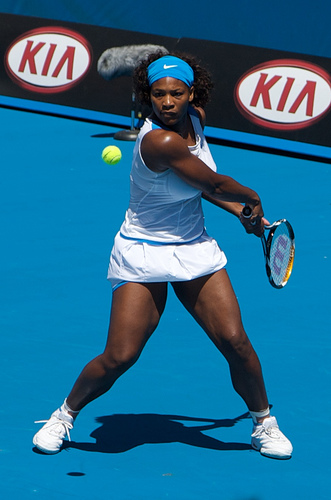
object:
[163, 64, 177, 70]
logo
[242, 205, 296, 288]
racket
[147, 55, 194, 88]
headband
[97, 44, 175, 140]
stand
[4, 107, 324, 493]
floor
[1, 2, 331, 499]
tennis court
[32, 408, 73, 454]
shoe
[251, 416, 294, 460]
shoe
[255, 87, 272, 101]
ground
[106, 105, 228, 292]
dress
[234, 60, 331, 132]
advertisement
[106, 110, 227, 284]
white dress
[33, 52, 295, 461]
lady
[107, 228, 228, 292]
skirt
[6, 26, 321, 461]
court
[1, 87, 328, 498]
ground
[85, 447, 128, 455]
shade edge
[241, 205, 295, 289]
tennis racket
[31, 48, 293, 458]
tennis player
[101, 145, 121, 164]
ball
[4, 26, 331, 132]
sign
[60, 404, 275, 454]
shadow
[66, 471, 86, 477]
shadow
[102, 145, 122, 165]
base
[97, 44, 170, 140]
furry stool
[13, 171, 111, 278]
part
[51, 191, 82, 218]
part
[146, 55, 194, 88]
head band